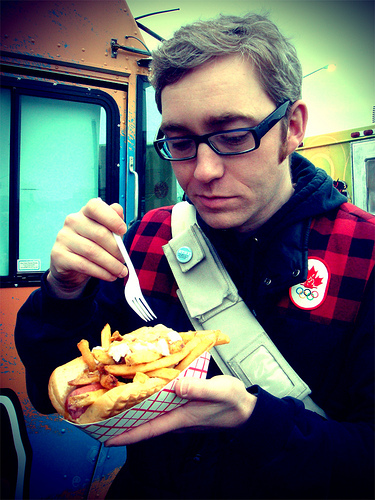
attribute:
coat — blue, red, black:
[12, 152, 373, 498]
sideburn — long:
[276, 106, 288, 163]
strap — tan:
[160, 200, 325, 415]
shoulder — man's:
[121, 202, 202, 283]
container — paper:
[114, 393, 146, 427]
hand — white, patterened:
[103, 391, 255, 451]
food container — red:
[53, 338, 212, 423]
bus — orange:
[0, 0, 154, 324]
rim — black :
[151, 126, 261, 163]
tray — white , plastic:
[58, 350, 214, 446]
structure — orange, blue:
[1, 0, 140, 195]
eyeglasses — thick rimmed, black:
[150, 100, 296, 162]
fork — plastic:
[111, 230, 156, 320]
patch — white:
[285, 255, 331, 311]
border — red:
[320, 259, 331, 304]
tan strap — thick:
[164, 249, 303, 399]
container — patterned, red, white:
[37, 99, 309, 463]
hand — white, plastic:
[49, 195, 129, 287]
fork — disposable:
[93, 196, 159, 322]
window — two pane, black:
[2, 70, 126, 292]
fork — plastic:
[109, 220, 158, 324]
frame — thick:
[11, 71, 124, 296]